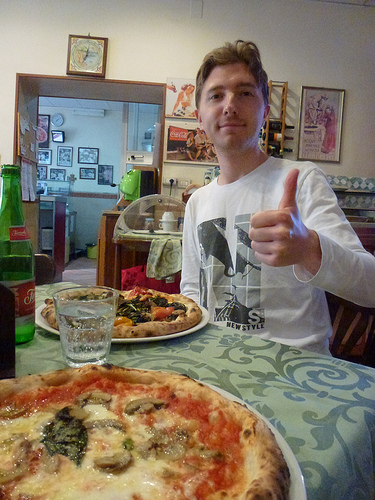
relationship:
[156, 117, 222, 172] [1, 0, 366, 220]
poster on wall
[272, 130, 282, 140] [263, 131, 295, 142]
label on wine bottle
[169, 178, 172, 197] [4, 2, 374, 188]
cord plugged into wall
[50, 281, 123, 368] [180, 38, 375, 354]
cup of guy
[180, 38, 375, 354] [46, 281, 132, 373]
guy in a glass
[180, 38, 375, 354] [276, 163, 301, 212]
guy giving a thumb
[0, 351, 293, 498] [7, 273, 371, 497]
pizza on table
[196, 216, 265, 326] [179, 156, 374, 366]
logo on a t-shirt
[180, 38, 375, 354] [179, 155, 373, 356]
guy wearing a shirt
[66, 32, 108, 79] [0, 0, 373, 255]
picture hanging on wall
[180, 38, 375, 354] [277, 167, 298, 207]
guy holding thumb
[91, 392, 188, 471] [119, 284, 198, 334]
mushrooms on a pizza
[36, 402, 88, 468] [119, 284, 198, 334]
spinach on a pizza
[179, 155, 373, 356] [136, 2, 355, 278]
shirt on a guy